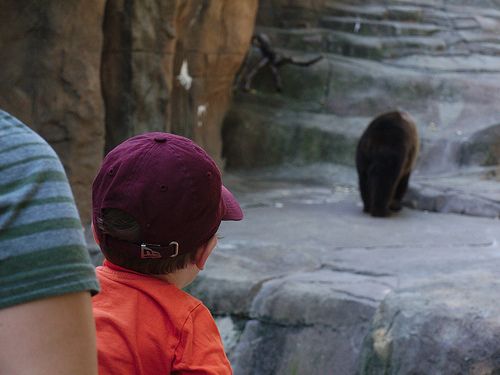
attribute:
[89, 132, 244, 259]
hat — purple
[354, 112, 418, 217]
bear — black, brown, large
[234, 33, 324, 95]
branch — dry, fallen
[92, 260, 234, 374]
shirt — orange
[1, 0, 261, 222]
rock — white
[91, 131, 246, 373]
boy — little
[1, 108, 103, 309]
shirt — green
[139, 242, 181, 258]
buckle — silver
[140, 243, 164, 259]
logo — silver